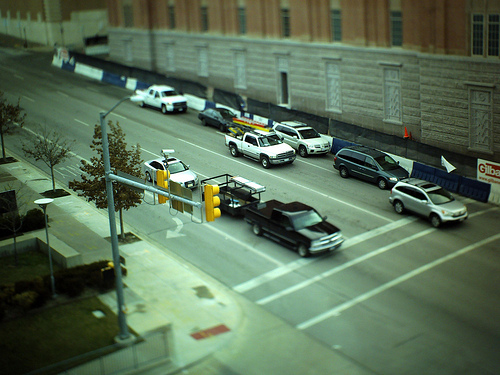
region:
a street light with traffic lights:
[97, 94, 220, 346]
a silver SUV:
[388, 176, 467, 228]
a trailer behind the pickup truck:
[200, 173, 265, 216]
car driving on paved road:
[387, 179, 469, 230]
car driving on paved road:
[332, 145, 410, 191]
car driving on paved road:
[270, 120, 329, 155]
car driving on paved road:
[224, 129, 293, 168]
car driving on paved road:
[245, 195, 344, 258]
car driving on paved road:
[144, 153, 199, 192]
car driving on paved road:
[199, 104, 237, 128]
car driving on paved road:
[143, 86, 189, 115]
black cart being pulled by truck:
[196, 170, 273, 221]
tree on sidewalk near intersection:
[69, 115, 148, 239]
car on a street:
[393, 173, 466, 233]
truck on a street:
[253, 200, 345, 265]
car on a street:
[190, 105, 231, 126]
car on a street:
[151, 141, 196, 186]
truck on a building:
[150, 76, 198, 111]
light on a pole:
[112, 88, 152, 115]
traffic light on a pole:
[200, 178, 226, 221]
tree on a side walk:
[22, 127, 81, 181]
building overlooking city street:
[0, 0, 496, 200]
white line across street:
[236, 198, 499, 331]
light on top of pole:
[99, 93, 149, 339]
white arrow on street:
[166, 216, 189, 239]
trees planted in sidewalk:
[1, 95, 141, 248]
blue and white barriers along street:
[56, 53, 499, 208]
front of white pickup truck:
[227, 123, 294, 165]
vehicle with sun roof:
[390, 180, 467, 227]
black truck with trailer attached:
[201, 164, 351, 261]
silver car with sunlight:
[147, 142, 197, 192]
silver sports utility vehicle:
[387, 171, 470, 227]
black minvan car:
[335, 141, 410, 191]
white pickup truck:
[225, 122, 295, 172]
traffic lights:
[86, 122, 223, 228]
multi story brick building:
[105, 2, 498, 203]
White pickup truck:
[138, 78, 190, 118]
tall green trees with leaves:
[75, 112, 141, 240]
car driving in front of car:
[245, 199, 344, 258]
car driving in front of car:
[389, 175, 467, 230]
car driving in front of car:
[330, 145, 411, 190]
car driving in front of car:
[272, 119, 330, 156]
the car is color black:
[238, 194, 351, 265]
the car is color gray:
[386, 171, 476, 233]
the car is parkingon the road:
[133, 81, 190, 120]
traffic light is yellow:
[196, 177, 229, 227]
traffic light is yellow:
[148, 162, 174, 207]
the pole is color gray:
[95, 104, 137, 350]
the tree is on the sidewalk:
[17, 122, 79, 207]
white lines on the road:
[343, 221, 459, 343]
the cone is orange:
[397, 121, 413, 143]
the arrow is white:
[161, 211, 190, 243]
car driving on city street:
[136, 83, 188, 114]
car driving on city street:
[198, 106, 240, 131]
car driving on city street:
[271, 119, 328, 157]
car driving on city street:
[389, 177, 469, 228]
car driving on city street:
[224, 124, 297, 170]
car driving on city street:
[143, 155, 200, 192]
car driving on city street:
[244, 198, 346, 258]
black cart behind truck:
[199, 172, 259, 218]